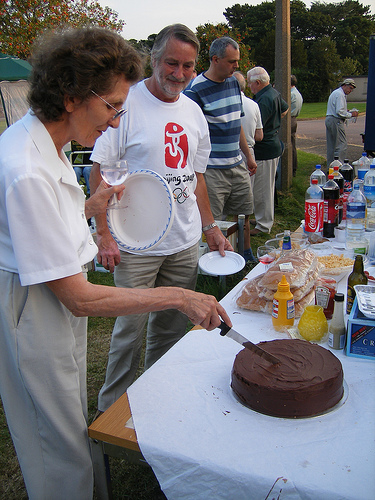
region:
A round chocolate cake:
[231, 333, 351, 421]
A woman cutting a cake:
[2, 22, 348, 428]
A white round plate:
[104, 166, 176, 256]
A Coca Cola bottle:
[297, 177, 330, 247]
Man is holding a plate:
[84, 20, 249, 280]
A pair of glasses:
[86, 83, 129, 126]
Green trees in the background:
[0, 0, 372, 101]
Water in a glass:
[97, 156, 133, 212]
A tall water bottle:
[341, 179, 369, 246]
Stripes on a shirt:
[181, 67, 247, 173]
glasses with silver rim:
[86, 87, 127, 123]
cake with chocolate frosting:
[232, 337, 343, 418]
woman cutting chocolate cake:
[0, 26, 346, 495]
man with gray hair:
[182, 34, 257, 270]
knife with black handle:
[218, 315, 282, 367]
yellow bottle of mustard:
[269, 276, 294, 332]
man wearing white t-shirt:
[88, 76, 211, 253]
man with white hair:
[243, 67, 267, 92]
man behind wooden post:
[291, 72, 303, 179]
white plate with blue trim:
[106, 168, 169, 249]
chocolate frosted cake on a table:
[229, 336, 346, 419]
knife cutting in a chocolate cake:
[193, 309, 346, 420]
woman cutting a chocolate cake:
[2, 26, 347, 499]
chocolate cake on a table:
[228, 336, 344, 421]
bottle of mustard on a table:
[270, 273, 295, 333]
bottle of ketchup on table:
[313, 273, 337, 319]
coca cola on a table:
[305, 195, 326, 244]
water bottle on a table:
[344, 181, 368, 248]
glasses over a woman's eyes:
[88, 91, 130, 118]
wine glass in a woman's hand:
[98, 158, 130, 211]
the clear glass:
[98, 159, 129, 210]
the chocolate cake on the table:
[230, 338, 343, 418]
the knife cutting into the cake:
[216, 318, 280, 364]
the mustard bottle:
[271, 275, 294, 332]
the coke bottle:
[303, 178, 322, 238]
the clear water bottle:
[345, 185, 365, 252]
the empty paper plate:
[106, 169, 174, 251]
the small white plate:
[198, 249, 244, 274]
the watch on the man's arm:
[201, 221, 217, 232]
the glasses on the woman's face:
[87, 88, 126, 120]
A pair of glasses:
[90, 91, 125, 117]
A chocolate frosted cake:
[231, 338, 344, 417]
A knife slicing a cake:
[214, 319, 279, 361]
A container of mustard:
[270, 274, 294, 330]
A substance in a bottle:
[298, 304, 327, 339]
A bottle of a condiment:
[329, 293, 345, 348]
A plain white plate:
[199, 250, 244, 274]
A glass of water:
[100, 161, 132, 208]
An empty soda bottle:
[304, 178, 323, 241]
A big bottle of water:
[346, 183, 364, 246]